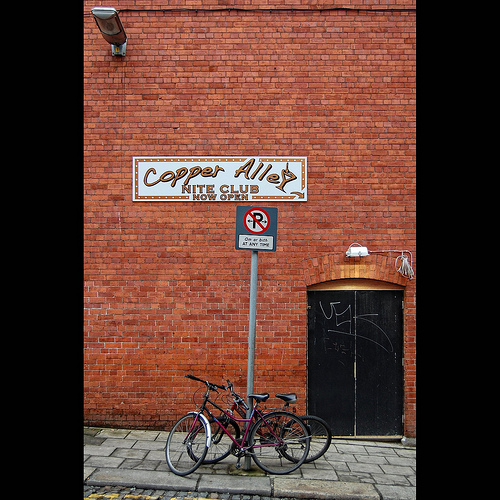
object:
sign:
[231, 199, 281, 251]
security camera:
[89, 5, 131, 57]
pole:
[243, 248, 259, 470]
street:
[85, 485, 417, 499]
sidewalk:
[84, 423, 415, 500]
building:
[85, 0, 416, 447]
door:
[306, 277, 404, 443]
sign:
[133, 157, 307, 202]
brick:
[208, 330, 222, 337]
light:
[91, 6, 129, 57]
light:
[347, 247, 370, 257]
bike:
[165, 374, 313, 477]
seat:
[247, 393, 270, 402]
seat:
[276, 392, 298, 402]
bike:
[187, 379, 332, 465]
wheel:
[165, 408, 212, 475]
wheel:
[249, 411, 311, 475]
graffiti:
[317, 299, 395, 355]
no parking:
[242, 236, 271, 248]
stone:
[130, 486, 142, 494]